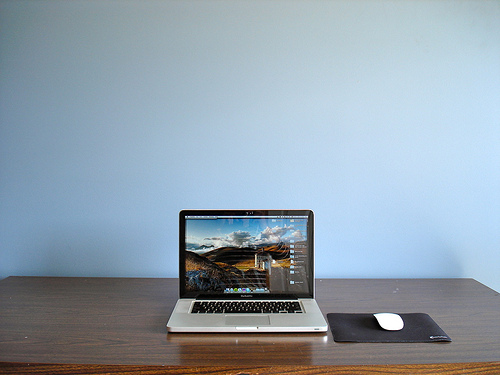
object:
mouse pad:
[326, 312, 451, 343]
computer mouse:
[373, 312, 405, 331]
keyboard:
[167, 295, 328, 332]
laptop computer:
[166, 208, 329, 334]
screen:
[180, 211, 315, 297]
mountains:
[187, 245, 290, 269]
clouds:
[186, 222, 302, 246]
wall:
[0, 0, 500, 295]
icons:
[224, 286, 269, 295]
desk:
[0, 275, 500, 372]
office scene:
[0, 0, 499, 372]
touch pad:
[227, 313, 272, 329]